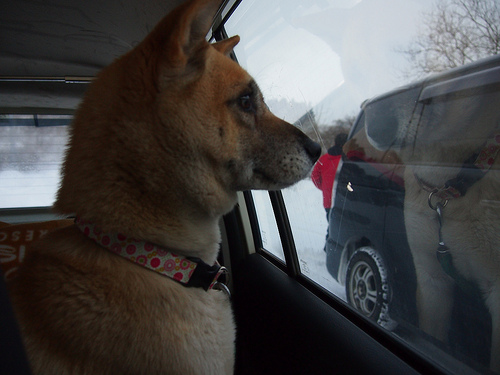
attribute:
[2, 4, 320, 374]
dog — brown, looking, blonde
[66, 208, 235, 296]
collar — colorful, green, wearing, white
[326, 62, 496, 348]
minivan — blue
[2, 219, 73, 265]
sign — orange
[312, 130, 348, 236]
man — standing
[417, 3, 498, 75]
tree — large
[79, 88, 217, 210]
hair — brown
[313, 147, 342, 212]
jacket — red